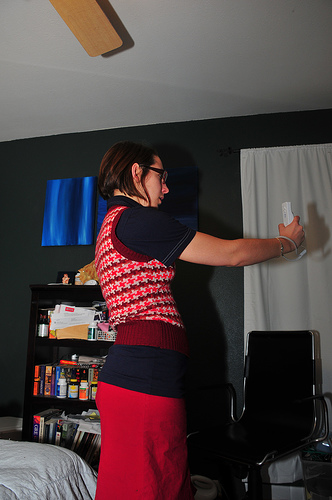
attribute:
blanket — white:
[28, 456, 68, 479]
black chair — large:
[221, 330, 324, 472]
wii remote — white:
[262, 193, 300, 253]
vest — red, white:
[91, 212, 183, 328]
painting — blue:
[40, 173, 114, 253]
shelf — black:
[34, 283, 44, 293]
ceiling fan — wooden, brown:
[54, 10, 155, 66]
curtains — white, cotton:
[261, 179, 302, 187]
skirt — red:
[89, 365, 199, 481]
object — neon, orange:
[52, 321, 98, 346]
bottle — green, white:
[93, 335, 96, 343]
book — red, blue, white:
[25, 416, 41, 439]